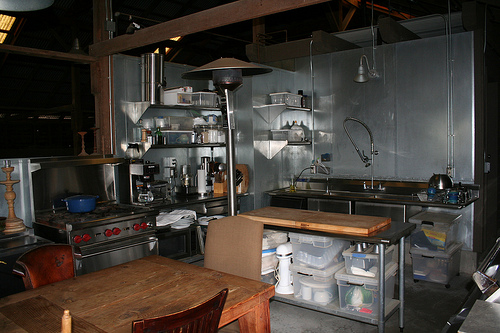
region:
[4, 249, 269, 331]
wood dining table in commercial kitchen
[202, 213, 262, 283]
chair with tapestry-covered back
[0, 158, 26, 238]
carved lamp on counter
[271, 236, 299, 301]
kitchen mixer under butcher block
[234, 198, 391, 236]
butcher block on steel table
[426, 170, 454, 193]
stainless steel bowl on drying rack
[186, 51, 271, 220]
outdoor heat lamp in kitchen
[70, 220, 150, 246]
red dials on kitchen stove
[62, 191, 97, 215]
dark blue enamel-coated dutch oven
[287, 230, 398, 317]
several large plastic tubs containing kitchen tools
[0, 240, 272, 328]
The table is made out of wood.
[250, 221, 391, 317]
Plastic containers on a shelf.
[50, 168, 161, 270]
A stainless steel oven.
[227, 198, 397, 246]
Wood board on the counter.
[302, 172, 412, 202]
A kitchen sink.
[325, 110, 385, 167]
A spray nossle for the sink.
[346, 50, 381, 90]
Lamp on the wall over the sink.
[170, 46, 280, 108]
A lamp with a shade on it.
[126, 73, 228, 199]
Shelves in the kitchen.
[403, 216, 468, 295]
Plastic boxes stacked on top of each other.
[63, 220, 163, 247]
Bright red stove knobs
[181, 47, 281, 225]
Tall silver heat lamp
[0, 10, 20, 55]
Yellow light on the ceiling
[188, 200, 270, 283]
Light brown chair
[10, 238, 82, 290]
Dark brown chair at table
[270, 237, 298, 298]
White kitchen mixer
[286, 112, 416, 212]
Silver sink next to the wall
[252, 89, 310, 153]
Metal shelves on wall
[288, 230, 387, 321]
Plastic storage containers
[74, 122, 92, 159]
Wooden candlestick on counter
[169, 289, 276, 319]
edge of brown chair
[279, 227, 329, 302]
plastic containers under table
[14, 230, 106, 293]
chair at brown table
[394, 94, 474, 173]
gray wall of kitchen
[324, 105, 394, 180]
long faucet at sink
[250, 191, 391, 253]
island of the kitchen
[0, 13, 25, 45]
yellow overhead lights at building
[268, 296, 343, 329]
gray floor of kitchen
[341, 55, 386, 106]
light thats turned off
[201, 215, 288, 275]
brown clear chair at table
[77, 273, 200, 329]
The table is wooden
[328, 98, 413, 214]
The sink is off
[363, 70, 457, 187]
The backsplash is metal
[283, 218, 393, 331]
The bins are clear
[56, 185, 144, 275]
The stove is off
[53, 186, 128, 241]
The pot is blue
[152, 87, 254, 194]
The shelves are full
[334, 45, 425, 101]
The light is off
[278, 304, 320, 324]
The floor is gray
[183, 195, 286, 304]
The chair is tan